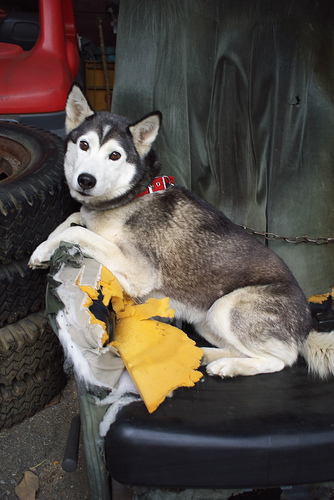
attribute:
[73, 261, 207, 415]
fabric — yellow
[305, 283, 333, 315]
fabric — yellow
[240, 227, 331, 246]
chain — metal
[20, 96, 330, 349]
dog — white and black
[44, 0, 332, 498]
chair — yellow, gray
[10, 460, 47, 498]
leaf — brown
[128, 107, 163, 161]
dog's ear — black edged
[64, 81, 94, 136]
dog's ear — black edged